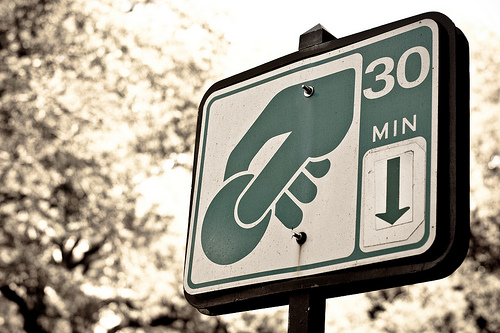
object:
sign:
[183, 11, 471, 333]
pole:
[287, 289, 326, 333]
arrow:
[374, 156, 410, 225]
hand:
[223, 68, 355, 229]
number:
[362, 45, 430, 99]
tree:
[0, 1, 184, 333]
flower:
[29, 105, 157, 246]